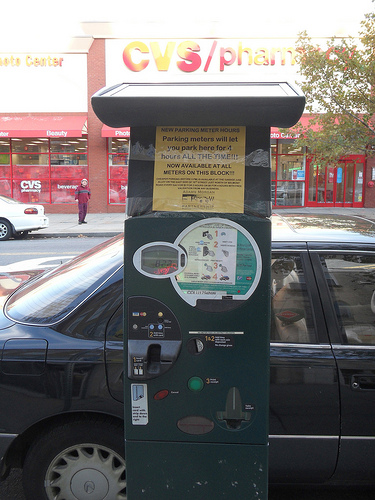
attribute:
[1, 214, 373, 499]
car — black, white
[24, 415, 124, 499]
wheel — back wheel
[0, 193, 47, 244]
car — white, sedan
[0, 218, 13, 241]
wheel — back wheel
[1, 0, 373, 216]
store — a building, cvs pharmacy, mainly red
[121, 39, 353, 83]
sign — on front, for cvs pharmacy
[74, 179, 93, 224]
man — standing, a pedestrian, watching, across the street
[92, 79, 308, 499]
parking meter — on the sidewalk, a box, green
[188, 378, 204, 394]
button — green, red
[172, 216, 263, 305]
instructions — numbered, step by step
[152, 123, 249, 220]
sign — yellow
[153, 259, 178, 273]
number — displayed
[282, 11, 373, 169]
tree — planted at curb, for shade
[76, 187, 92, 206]
shirt — red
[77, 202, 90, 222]
pants — purple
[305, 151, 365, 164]
frame — red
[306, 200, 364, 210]
frame — red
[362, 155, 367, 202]
frame — red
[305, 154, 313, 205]
frame — red